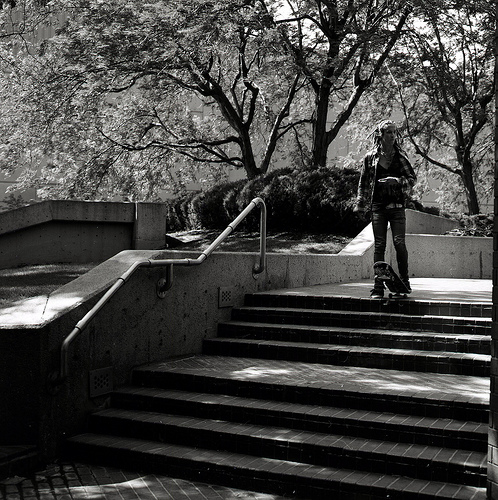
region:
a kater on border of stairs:
[343, 114, 429, 309]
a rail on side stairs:
[44, 188, 280, 420]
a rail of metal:
[51, 188, 275, 392]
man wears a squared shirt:
[338, 116, 426, 252]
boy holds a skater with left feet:
[347, 114, 422, 307]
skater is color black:
[366, 249, 412, 304]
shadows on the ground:
[318, 239, 486, 313]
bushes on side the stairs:
[145, 151, 366, 244]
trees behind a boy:
[87, 13, 496, 301]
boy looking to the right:
[349, 109, 428, 303]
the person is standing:
[323, 109, 423, 279]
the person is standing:
[340, 99, 450, 382]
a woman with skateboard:
[329, 90, 416, 312]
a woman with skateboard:
[308, 94, 458, 354]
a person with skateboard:
[341, 110, 447, 330]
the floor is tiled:
[53, 466, 144, 496]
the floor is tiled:
[191, 387, 304, 462]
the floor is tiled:
[175, 313, 301, 383]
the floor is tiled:
[315, 354, 450, 424]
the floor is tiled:
[210, 372, 360, 445]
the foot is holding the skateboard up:
[371, 248, 430, 301]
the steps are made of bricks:
[261, 398, 325, 427]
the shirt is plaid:
[398, 156, 414, 178]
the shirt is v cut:
[376, 155, 398, 176]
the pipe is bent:
[204, 193, 280, 279]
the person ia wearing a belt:
[385, 197, 405, 212]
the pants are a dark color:
[390, 217, 403, 246]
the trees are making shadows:
[311, 275, 466, 383]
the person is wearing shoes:
[365, 281, 387, 301]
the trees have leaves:
[100, 16, 138, 48]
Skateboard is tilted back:
[361, 254, 416, 310]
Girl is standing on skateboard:
[352, 114, 418, 308]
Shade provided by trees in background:
[11, 16, 389, 258]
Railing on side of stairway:
[28, 160, 275, 443]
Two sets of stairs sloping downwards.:
[36, 235, 488, 496]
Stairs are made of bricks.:
[43, 326, 378, 481]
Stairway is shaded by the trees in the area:
[8, 189, 475, 490]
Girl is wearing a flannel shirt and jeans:
[341, 106, 433, 309]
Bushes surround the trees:
[136, 158, 492, 251]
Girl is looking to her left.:
[336, 106, 476, 307]